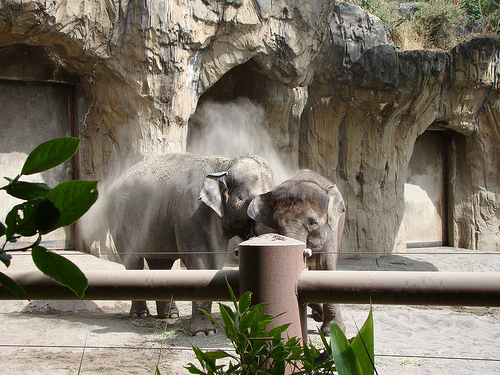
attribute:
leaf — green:
[25, 139, 81, 175]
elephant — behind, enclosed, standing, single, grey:
[111, 146, 268, 337]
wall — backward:
[10, 2, 498, 254]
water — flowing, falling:
[193, 88, 286, 180]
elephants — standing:
[102, 143, 347, 339]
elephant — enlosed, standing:
[256, 163, 359, 336]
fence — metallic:
[0, 234, 498, 375]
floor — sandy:
[0, 248, 499, 374]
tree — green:
[218, 282, 307, 374]